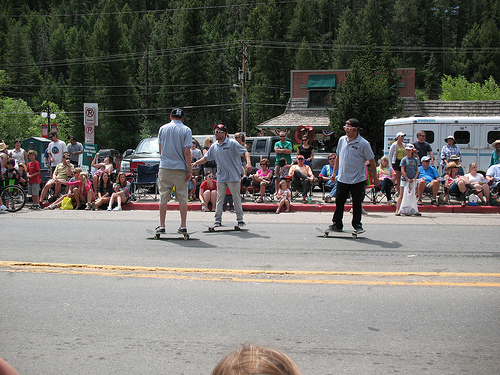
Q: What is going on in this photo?
A: Skateboarding with viewers.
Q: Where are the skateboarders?
A: On the road.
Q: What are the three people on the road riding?
A: Skateboards.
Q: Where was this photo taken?
A: At an outdoor event.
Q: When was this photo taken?
A: Outside, during the daytime.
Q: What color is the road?
A: Gray.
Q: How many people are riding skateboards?
A: Three.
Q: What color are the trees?
A: Green.